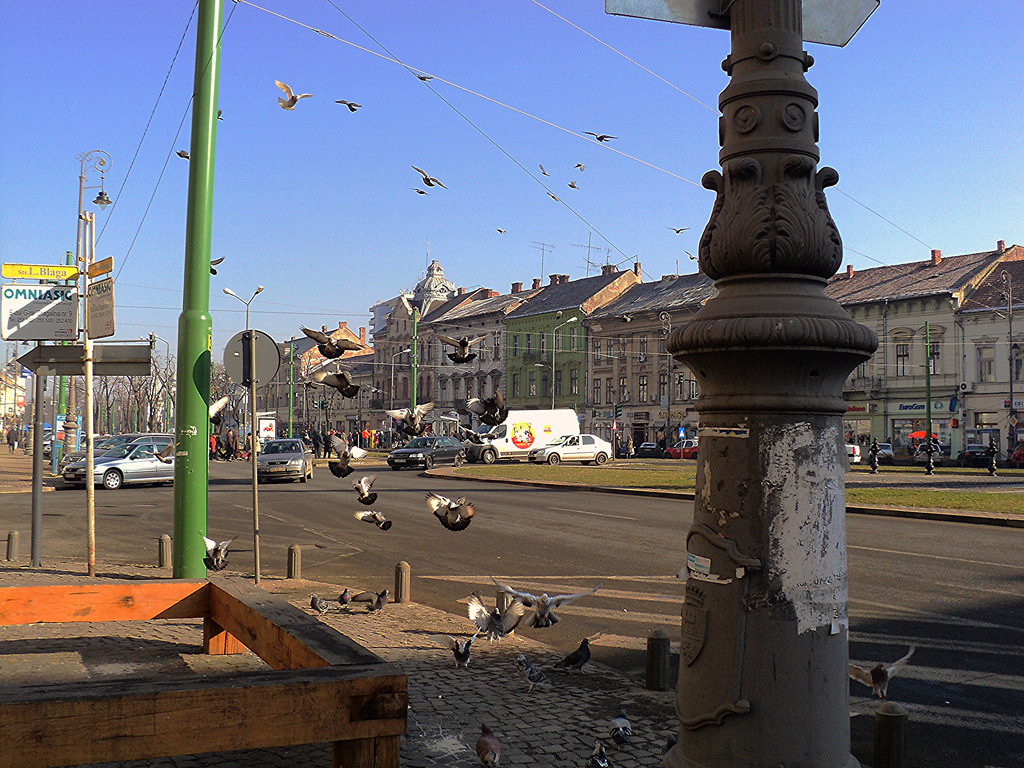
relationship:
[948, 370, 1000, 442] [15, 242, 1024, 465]
wall on side building